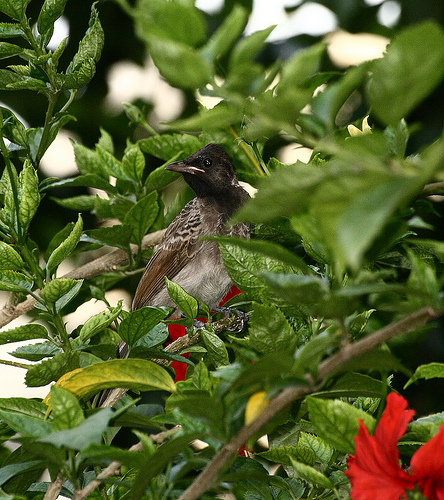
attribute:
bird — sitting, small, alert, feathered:
[117, 141, 262, 346]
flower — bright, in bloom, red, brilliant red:
[338, 387, 444, 494]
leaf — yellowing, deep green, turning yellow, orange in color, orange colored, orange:
[41, 360, 175, 402]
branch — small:
[146, 294, 433, 498]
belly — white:
[157, 233, 255, 315]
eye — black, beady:
[202, 157, 212, 170]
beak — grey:
[165, 157, 207, 173]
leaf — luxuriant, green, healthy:
[364, 21, 444, 126]